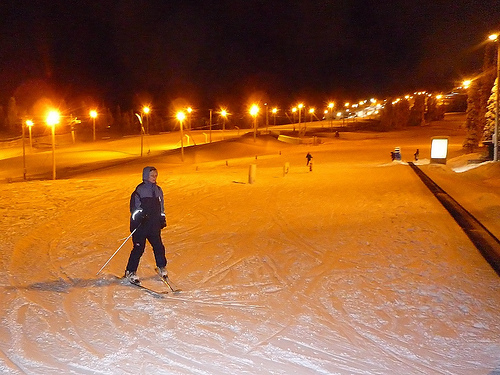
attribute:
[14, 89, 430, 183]
light row — long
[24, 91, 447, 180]
lights — on, orange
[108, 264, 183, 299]
skis — white, turned in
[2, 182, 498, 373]
snow — white, packed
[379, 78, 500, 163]
trees — lined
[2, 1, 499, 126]
sky — dark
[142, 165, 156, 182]
hood — up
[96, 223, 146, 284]
ski pole — shiny chrome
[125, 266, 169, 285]
boots — white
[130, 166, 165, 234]
jacket — blue, purple, black, grey, gray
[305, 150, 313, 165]
person — running, far, skiing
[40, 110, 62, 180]
light — on, orange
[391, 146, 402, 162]
trash cans — blue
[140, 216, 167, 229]
gloves — black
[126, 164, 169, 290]
woman — skiing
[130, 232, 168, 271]
pants — black